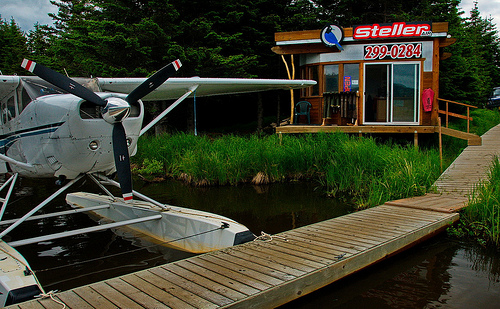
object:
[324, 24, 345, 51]
bird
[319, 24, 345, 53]
logo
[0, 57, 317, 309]
airplane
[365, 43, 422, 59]
number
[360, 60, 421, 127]
door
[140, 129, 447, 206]
grass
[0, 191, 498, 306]
water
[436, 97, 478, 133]
fence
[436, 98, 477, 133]
hand rail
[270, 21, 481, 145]
building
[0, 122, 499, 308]
boardwalk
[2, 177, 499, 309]
lake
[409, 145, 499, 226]
ground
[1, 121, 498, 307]
dock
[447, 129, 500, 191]
road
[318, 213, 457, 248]
walkway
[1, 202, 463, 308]
bridge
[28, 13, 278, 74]
leaves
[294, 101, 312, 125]
chair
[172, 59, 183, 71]
stripes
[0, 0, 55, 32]
sky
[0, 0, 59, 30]
clouds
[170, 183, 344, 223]
water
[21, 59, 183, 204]
blade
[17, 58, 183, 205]
propeller